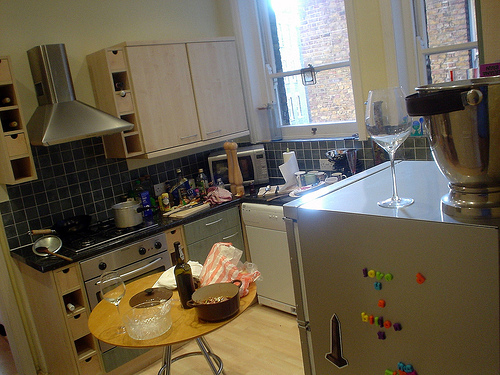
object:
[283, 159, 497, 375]
fridge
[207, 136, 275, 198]
corner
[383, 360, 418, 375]
magnets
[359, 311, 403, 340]
magnets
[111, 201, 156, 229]
cooker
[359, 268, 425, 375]
letters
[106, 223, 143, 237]
stove burner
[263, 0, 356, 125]
window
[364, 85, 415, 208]
glass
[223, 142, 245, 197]
mills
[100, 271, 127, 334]
glass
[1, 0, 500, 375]
kitchen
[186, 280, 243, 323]
lid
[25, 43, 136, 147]
chimney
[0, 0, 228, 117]
wall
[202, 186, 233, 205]
rag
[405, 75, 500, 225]
ice bucket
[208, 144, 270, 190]
microwave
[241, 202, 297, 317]
dishwasher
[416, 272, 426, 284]
stickies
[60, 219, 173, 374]
oven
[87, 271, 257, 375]
table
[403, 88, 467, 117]
handle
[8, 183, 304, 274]
counter top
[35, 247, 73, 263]
spoon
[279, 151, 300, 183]
holder